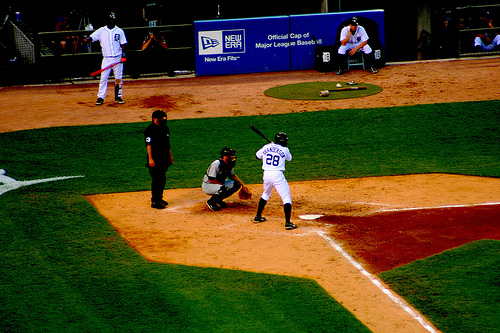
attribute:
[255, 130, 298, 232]
player — playing, batting, waiting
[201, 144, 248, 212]
catcher — waiting, posistioned, posisitioned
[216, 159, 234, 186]
gear — black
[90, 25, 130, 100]
uniform — white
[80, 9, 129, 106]
player — waiting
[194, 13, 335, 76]
advertisement — blue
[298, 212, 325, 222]
plate — diamond, white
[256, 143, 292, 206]
uniform — white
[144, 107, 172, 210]
umpire — standing, watching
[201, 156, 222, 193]
uniform — grey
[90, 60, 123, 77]
bat — red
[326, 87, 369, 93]
bat — laying